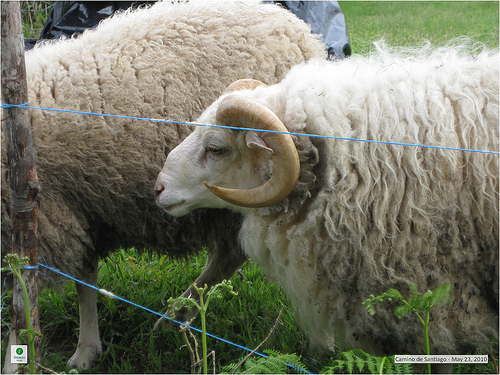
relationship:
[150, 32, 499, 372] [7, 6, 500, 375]
sheep stands by fence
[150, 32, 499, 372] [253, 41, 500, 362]
sheep has fur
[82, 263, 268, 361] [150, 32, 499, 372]
grass beside sheep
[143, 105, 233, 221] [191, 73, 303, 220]
face with horns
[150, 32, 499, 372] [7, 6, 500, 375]
sheep needs sharing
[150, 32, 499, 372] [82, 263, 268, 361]
sheep in grass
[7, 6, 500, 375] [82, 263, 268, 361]
sheeps in grass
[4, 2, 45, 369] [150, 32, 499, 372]
fencepost in front sheep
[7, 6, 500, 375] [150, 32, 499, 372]
fenceline keep sheep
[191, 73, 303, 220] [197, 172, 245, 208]
horn has a tip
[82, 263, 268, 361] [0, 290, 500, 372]
grass in field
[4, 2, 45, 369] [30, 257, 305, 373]
pole holding rope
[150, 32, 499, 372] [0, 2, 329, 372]
sheep next to sheep